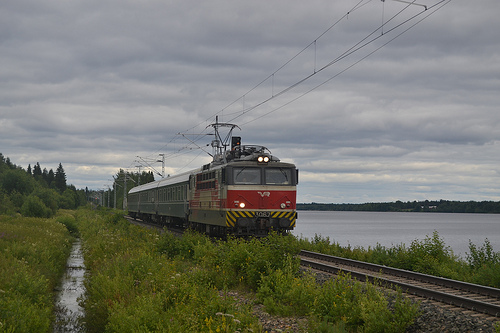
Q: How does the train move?
A: On tracks.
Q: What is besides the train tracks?
A: Body of water.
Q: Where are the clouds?
A: In sky.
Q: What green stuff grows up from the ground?
A: Grass.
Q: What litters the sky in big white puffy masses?
A: Clouds.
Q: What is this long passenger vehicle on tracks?
A: Train.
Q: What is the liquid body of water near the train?
A: Water.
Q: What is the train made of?
A: Metal.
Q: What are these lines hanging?
A: Power lines.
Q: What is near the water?
A: Train.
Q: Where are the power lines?
A: Above train.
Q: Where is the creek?
A: Near railroad.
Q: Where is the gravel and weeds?
A: On side of railroad.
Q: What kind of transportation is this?
A: A train.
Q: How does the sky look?
A: Overcast.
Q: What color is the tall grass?
A: Green.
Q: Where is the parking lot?
A: There isn't one.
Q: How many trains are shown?
A: 1.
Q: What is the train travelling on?
A: Tracks.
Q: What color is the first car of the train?
A: Red.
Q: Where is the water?
A: Beside the train tracks.